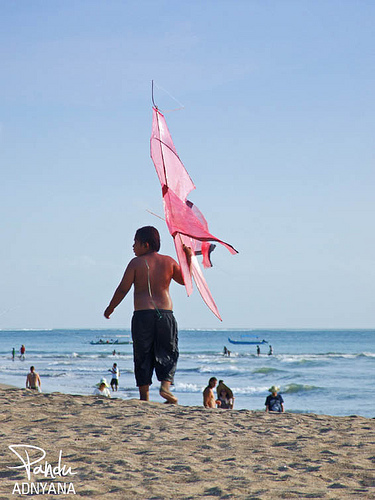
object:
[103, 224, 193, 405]
boy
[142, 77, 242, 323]
kite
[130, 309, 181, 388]
pants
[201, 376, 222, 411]
people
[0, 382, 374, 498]
beach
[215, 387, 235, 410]
woman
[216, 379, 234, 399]
hat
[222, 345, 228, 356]
people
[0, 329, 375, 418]
ocean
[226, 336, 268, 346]
boat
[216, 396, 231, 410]
shirt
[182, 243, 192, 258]
right hand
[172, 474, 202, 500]
sand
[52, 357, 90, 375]
waves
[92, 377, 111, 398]
person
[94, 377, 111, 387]
brimmed hat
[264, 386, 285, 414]
person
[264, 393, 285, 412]
shirt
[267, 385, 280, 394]
brimmed hat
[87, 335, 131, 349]
boat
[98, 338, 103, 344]
people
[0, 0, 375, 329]
sky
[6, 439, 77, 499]
watermark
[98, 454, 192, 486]
footprints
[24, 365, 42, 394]
man